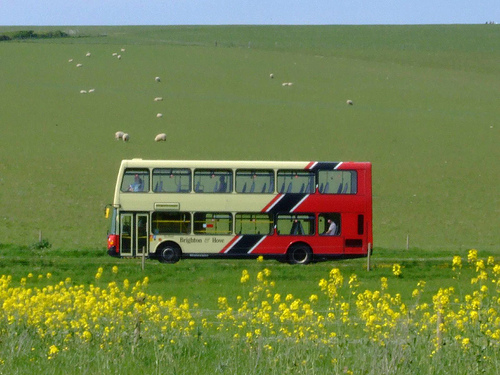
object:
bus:
[105, 157, 373, 266]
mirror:
[102, 205, 115, 221]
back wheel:
[284, 240, 313, 265]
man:
[320, 219, 338, 236]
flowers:
[3, 253, 498, 374]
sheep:
[150, 131, 168, 142]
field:
[0, 25, 499, 255]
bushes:
[0, 25, 79, 43]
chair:
[240, 180, 252, 193]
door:
[116, 212, 151, 258]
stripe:
[104, 157, 374, 265]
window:
[119, 167, 151, 195]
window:
[149, 209, 191, 237]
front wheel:
[154, 243, 184, 263]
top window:
[233, 168, 277, 196]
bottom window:
[233, 211, 273, 236]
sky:
[0, 0, 499, 25]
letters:
[179, 236, 223, 245]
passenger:
[214, 175, 226, 193]